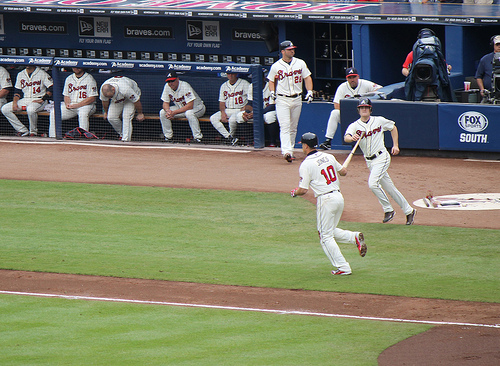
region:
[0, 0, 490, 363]
active Braves baseball game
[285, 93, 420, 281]
running Braves baseball players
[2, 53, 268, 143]
benched Braves baseball players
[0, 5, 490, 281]
Braves baseball game in progress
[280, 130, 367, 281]
Braves player number ten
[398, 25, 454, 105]
baseball camera man with cover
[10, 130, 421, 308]
baseball player running on the grass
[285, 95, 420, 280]
baseball players dressed in white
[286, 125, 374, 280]
baseball player in black helmet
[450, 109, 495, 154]
Fox Sports South sign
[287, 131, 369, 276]
the player is running on the field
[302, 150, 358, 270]
the player is wearing an outfit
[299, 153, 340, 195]
the player is wearing a short sleeve shirt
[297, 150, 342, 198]
the shirt is white in color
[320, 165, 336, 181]
a number is on the shirt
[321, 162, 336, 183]
the number is red in color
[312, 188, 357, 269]
the player is wearing long pants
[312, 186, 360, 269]
the pants are white in color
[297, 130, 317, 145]
the player is wearing a helmet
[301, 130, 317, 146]
the helmet is black in color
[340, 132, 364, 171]
Light beige baseball bat.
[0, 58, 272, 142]
Players sitting in dugout.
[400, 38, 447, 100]
Camera with blue cloth over it.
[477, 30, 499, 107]
Camera man in blue shirt.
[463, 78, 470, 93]
Red and white cup near camera man.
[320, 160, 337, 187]
The number '10' in red.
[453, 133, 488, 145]
The word 'South' written in white.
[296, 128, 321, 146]
Blue baseball helmet worn by player with 10 on uniform.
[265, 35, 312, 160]
Baseball player walking from dugout.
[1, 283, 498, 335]
White line painted on field.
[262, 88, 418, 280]
the players on the field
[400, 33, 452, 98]
the camera on the sideline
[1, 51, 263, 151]
the railing of the dug out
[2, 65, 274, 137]
the players in the dug out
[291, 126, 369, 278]
the player is running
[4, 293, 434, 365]
the grass on the field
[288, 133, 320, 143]
the player wearing the helmet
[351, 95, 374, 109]
the player wearing the helmet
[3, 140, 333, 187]
the dirt on the field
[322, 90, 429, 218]
the player holding the bat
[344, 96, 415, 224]
a baseball player running on a field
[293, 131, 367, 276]
a baseball player wearing a white uniform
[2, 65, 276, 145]
baseball player sitting in the dugout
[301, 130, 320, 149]
man wearing a black hard hat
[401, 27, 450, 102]
a cameraman behind a TV camera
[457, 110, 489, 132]
a white logo on a blue wall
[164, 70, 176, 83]
man wearing a blue and red cap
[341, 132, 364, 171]
a wooden baseball bat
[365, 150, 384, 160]
man wearing a black belt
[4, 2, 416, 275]
baseball players wearing white uniforms